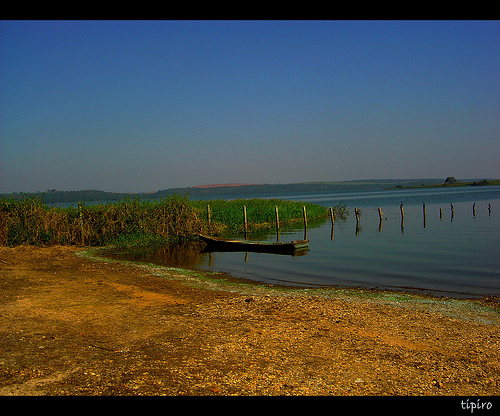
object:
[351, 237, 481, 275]
water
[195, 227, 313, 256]
boat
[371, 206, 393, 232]
stump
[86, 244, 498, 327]
shore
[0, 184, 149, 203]
mountians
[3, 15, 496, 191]
sky